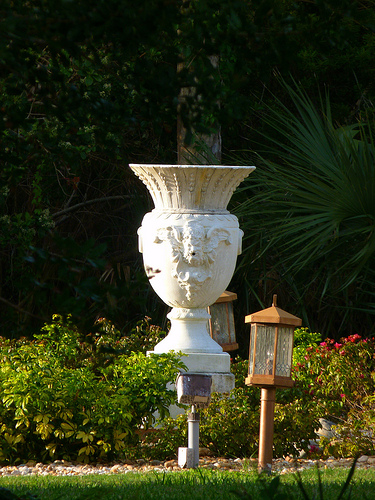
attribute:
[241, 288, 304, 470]
light — octagonal, small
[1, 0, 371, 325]
tree — small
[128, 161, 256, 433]
structure — white, large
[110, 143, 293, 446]
vase — Large, concrete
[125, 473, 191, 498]
grass — tall, green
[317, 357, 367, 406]
plants — short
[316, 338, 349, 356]
flowers — red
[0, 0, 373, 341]
green thicket — dark green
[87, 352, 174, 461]
bush — Large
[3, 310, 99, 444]
bush — Large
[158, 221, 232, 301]
carving — intricate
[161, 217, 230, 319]
carving — intricate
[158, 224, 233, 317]
carving — intricate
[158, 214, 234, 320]
carving — intricate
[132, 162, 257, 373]
birdbath — large, stone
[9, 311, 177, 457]
bush — small, green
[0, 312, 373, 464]
shrubbery — is thick, is green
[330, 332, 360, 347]
flowers — pink, red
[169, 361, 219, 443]
light — single, white, brown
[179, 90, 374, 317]
palm tree — large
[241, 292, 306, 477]
brown accessory — light brown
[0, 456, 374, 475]
rocks — white, tan, oval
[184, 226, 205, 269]
sculture — face 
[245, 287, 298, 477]
light — small, golden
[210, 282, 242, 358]
light — small, golden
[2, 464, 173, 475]
pebbles — light colored, smooth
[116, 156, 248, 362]
structure — white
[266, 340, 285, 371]
bulb — small, light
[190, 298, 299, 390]
lights — outdoor, bronze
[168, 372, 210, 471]
spotlight — back-facing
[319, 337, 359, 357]
flowers — Hot pink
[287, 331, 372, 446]
leaves — green 